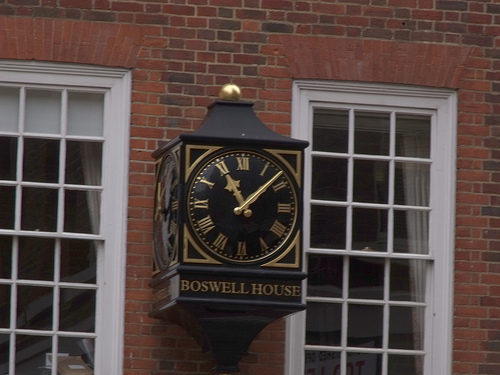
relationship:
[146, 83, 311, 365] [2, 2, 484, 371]
clock standing outside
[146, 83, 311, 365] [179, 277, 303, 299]
clock says boswell house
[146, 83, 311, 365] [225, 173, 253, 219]
clock has hand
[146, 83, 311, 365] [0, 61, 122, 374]
clock next to window pane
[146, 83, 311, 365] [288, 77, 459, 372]
clock next to window pane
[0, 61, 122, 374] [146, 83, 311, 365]
window pane next to clock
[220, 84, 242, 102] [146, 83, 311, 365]
ball on top of clock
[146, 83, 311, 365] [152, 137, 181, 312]
clock has side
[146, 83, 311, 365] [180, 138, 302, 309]
clock has side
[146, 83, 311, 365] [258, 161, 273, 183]
clock has number i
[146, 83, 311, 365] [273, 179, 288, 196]
clock has number ii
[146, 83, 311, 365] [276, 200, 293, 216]
clock has number iii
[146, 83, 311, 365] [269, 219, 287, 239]
clock has number iiii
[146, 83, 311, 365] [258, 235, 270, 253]
clock has number v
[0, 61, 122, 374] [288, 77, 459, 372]
window pane next to window pane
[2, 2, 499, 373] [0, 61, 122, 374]
wall has window pane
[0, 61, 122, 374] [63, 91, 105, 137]
window pane has square pane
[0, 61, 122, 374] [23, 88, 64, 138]
window pane has square pane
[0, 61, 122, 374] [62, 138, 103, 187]
window pane has square pane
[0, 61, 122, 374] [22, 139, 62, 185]
window pane has square pane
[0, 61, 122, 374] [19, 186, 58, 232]
window pane has square pane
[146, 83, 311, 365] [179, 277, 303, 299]
clock has boswell house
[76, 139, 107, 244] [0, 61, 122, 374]
curtain inside window pane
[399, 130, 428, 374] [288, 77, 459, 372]
curtain inside window pane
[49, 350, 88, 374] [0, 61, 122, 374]
package in window pane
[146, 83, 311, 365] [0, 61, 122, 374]
clock between window pane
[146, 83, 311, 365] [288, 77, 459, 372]
clock between window pane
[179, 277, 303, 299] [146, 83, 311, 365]
boswell house under clock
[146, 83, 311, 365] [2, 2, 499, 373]
clock on wall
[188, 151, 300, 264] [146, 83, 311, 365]
clock face on clock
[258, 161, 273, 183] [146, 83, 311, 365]
number i printed on clock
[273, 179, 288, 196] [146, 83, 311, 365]
number ii printed on clock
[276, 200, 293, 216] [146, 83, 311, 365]
number iii printed on clock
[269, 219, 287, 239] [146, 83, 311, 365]
number iiii printed on clock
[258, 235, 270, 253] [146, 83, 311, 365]
number v printed on clock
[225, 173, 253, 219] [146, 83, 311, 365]
hand on clock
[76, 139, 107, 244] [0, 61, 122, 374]
curtain hanging on window pane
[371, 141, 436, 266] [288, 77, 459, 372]
reflection reflected on window pane